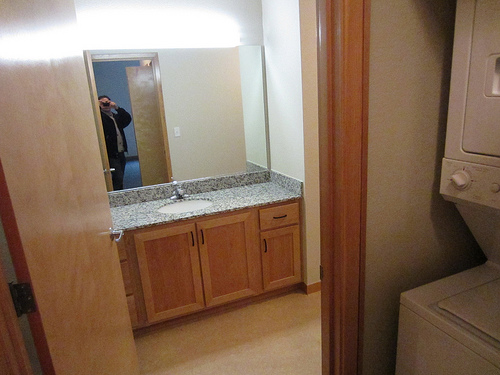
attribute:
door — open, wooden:
[0, 2, 147, 373]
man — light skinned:
[96, 94, 133, 186]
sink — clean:
[156, 195, 215, 215]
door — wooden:
[2, 52, 164, 372]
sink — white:
[138, 182, 253, 239]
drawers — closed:
[258, 206, 305, 227]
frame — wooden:
[316, 0, 370, 373]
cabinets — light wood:
[117, 197, 304, 332]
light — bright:
[72, 8, 254, 73]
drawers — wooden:
[76, 181, 306, 304]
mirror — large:
[91, 47, 269, 198]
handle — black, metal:
[184, 229, 197, 249]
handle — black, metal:
[195, 225, 206, 246]